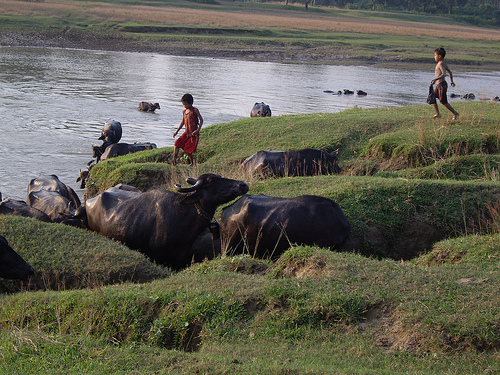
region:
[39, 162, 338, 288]
hippos on the ground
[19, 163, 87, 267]
black hippo by the water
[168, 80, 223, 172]
boy in red in the grass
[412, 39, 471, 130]
boy in the grass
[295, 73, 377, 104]
cows in the water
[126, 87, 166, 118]
cows in the water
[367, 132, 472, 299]
grass in the ground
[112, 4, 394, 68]
grass in the distance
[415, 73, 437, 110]
shirt on the boys hand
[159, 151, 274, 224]
horns on the head of a cow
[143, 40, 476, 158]
Two boys in the grass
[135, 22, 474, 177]
two boys in the water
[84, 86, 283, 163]
cows in the water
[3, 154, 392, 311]
cows in the hillside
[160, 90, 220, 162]
a boy in red clothing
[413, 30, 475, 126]
a boy wearing shorts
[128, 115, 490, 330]
a grassy hillside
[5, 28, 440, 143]
a lake with cows in it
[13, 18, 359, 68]
the bank of a lake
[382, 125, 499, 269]
tall grass on a hillside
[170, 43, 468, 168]
Short native island children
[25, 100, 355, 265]
Island mammals being herded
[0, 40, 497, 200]
Calm and clear river water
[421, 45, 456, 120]
Boy walking with shirt in hand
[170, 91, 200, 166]
Boy in red outfit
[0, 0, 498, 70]
Flat grass and dirt riverland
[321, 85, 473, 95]
Rocks in the river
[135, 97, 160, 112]
Lone mammal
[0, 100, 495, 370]
Hills covered with grass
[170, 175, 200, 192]
Short brown animal horns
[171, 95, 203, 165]
a boy wearing red shorts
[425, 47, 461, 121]
a boy is wearing shorts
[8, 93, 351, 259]
a boy and water buffalo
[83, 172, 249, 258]
a black water buffalo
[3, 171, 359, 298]
a group of water buffalo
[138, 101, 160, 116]
a water buffalo in the water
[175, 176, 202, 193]
a horn of the water buffalo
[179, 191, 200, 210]
an ear of the water buffalo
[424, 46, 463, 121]
a boy holding something while walking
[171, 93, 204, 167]
a boy near the water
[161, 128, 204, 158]
boy in red pants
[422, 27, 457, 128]
boy is walking to edge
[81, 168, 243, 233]
animal looking up at boy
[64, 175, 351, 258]
two animals walking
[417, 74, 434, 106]
boy carrying a shirt in hand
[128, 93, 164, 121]
animal in the water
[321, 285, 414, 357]
dirt patches in the grass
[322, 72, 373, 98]
animals are in the water